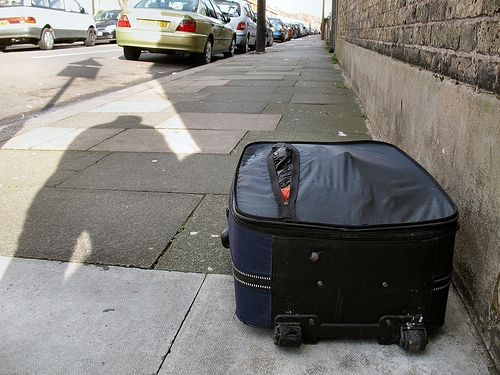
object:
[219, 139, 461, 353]
blue luggage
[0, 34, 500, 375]
sidewalk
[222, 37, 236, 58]
wheels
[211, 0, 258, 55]
car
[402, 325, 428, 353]
wheel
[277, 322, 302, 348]
wheel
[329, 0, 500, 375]
building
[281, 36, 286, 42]
wheels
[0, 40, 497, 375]
ground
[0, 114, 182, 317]
shadows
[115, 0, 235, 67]
car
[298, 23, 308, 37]
cars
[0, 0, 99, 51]
mini van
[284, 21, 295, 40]
car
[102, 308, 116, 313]
spot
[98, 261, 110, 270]
spot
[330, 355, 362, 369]
spot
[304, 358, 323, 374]
spot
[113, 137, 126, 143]
spot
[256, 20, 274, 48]
cars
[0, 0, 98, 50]
cars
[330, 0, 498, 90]
brick wall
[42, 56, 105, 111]
shadow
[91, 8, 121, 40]
car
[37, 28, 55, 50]
wheel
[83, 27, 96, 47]
wheel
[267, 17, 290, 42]
car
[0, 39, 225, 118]
street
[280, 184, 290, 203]
object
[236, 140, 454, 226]
compartment